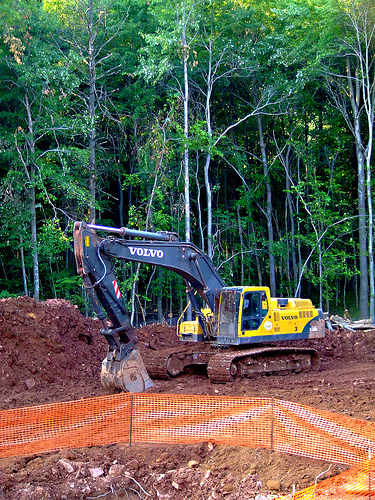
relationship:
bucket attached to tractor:
[99, 347, 155, 392] [71, 220, 327, 393]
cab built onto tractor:
[214, 285, 273, 346] [71, 220, 327, 393]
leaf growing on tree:
[167, 39, 172, 43] [133, 1, 204, 320]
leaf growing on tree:
[140, 34, 144, 38] [133, 1, 204, 320]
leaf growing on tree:
[159, 8, 165, 11] [133, 1, 204, 320]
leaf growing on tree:
[197, 20, 199, 23] [133, 1, 204, 320]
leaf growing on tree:
[140, 56, 143, 58] [133, 1, 204, 320]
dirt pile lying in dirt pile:
[0, 295, 361, 400] [0, 295, 361, 400]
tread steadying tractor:
[205, 345, 321, 383] [71, 220, 327, 393]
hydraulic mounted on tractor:
[84, 223, 170, 240] [71, 220, 327, 393]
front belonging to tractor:
[175, 286, 243, 346] [71, 220, 327, 393]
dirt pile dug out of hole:
[0, 295, 361, 400] [1, 444, 352, 498]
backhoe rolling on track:
[70, 219, 326, 392] [143, 342, 207, 380]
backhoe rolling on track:
[70, 219, 326, 392] [206, 345, 322, 382]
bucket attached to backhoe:
[99, 347, 155, 392] [70, 219, 326, 392]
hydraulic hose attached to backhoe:
[81, 237, 108, 289] [70, 219, 326, 392]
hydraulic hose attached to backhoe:
[105, 232, 224, 286] [70, 219, 326, 392]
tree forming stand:
[128, 0, 211, 321] [1, 2, 363, 326]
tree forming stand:
[221, 0, 285, 295] [1, 2, 363, 326]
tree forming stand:
[264, 0, 362, 317] [1, 2, 363, 326]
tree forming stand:
[2, 0, 57, 300] [1, 2, 363, 326]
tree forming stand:
[39, 0, 133, 318] [1, 2, 363, 326]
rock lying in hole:
[87, 467, 104, 479] [1, 444, 352, 498]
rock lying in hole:
[58, 456, 74, 472] [1, 444, 352, 498]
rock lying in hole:
[68, 482, 76, 488] [1, 444, 352, 498]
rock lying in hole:
[185, 458, 199, 468] [1, 444, 352, 498]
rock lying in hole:
[170, 479, 184, 490] [1, 444, 352, 498]